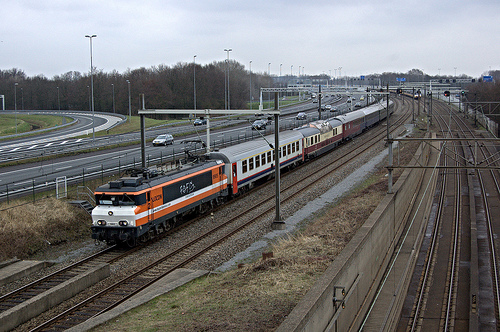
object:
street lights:
[440, 87, 470, 104]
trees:
[0, 69, 17, 110]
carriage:
[192, 124, 309, 203]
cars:
[152, 130, 174, 147]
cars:
[191, 115, 204, 125]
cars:
[247, 117, 269, 130]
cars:
[327, 104, 339, 114]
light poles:
[70, 26, 279, 119]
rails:
[128, 97, 293, 223]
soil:
[267, 196, 382, 274]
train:
[90, 99, 390, 246]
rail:
[391, 96, 499, 330]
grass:
[114, 171, 384, 331]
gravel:
[118, 172, 403, 330]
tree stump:
[260, 248, 277, 266]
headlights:
[93, 212, 142, 228]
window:
[238, 158, 250, 174]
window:
[251, 157, 255, 170]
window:
[260, 150, 267, 170]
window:
[265, 150, 275, 162]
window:
[277, 147, 287, 161]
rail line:
[124, 281, 158, 297]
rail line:
[37, 260, 70, 280]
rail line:
[126, 263, 161, 280]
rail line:
[104, 249, 129, 269]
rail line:
[167, 239, 200, 259]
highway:
[0, 88, 377, 193]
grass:
[229, 252, 294, 294]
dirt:
[188, 297, 276, 325]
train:
[96, 75, 493, 291]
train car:
[201, 128, 304, 195]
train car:
[288, 117, 340, 159]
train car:
[330, 109, 367, 141]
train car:
[358, 104, 380, 130]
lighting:
[84, 26, 101, 134]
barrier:
[277, 126, 434, 330]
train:
[396, 84, 423, 101]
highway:
[10, 100, 140, 176]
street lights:
[218, 47, 305, 109]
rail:
[3, 86, 420, 330]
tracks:
[387, 162, 499, 253]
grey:
[3, 3, 491, 72]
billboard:
[394, 75, 407, 81]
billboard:
[480, 74, 492, 82]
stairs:
[67, 196, 97, 203]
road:
[0, 111, 120, 164]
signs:
[394, 71, 409, 84]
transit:
[79, 97, 432, 244]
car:
[148, 128, 180, 150]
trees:
[230, 60, 238, 110]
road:
[1, 87, 355, 215]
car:
[132, 130, 179, 164]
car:
[248, 113, 273, 131]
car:
[181, 113, 210, 136]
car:
[282, 99, 316, 135]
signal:
[330, 281, 352, 311]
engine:
[87, 151, 229, 250]